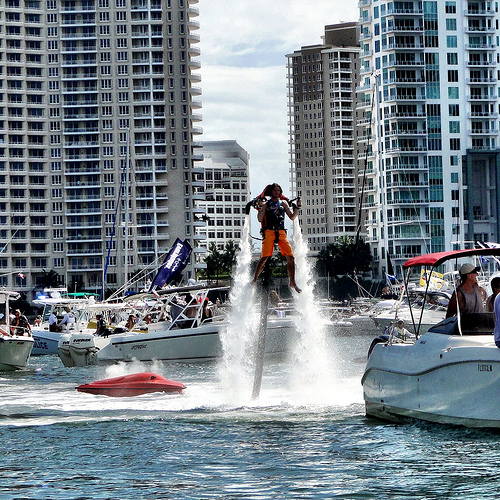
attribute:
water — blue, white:
[2, 344, 500, 498]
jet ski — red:
[75, 362, 178, 402]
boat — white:
[347, 251, 500, 441]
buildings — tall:
[0, 3, 500, 299]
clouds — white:
[195, 18, 286, 132]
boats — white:
[1, 260, 500, 418]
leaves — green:
[340, 241, 376, 269]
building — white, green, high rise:
[371, 6, 492, 279]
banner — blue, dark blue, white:
[148, 240, 188, 291]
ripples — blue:
[17, 426, 499, 497]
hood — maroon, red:
[395, 247, 500, 268]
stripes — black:
[108, 323, 287, 360]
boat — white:
[79, 290, 300, 363]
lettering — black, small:
[475, 361, 500, 373]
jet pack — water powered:
[242, 199, 302, 236]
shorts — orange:
[260, 221, 292, 256]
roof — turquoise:
[40, 290, 86, 300]